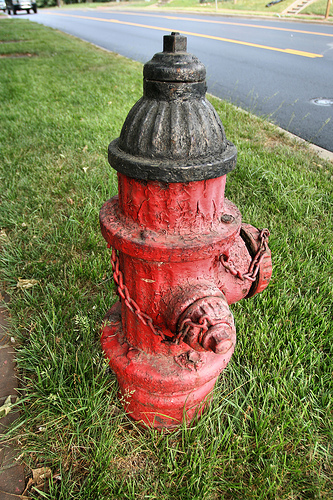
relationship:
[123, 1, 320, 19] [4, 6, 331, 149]
sidewalk runs along road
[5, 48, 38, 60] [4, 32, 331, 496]
hole in grass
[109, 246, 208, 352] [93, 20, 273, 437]
chain on fire hydrant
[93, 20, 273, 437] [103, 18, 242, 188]
fire hydrant has hydrant top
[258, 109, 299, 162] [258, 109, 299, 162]
curb at curb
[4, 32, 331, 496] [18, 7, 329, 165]
grass on either side of street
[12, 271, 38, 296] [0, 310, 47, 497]
leave on cement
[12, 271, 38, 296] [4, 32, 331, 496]
leave on grass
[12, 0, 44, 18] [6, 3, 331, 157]
car drives on street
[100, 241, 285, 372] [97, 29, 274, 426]
chain connecting valves on fire hydrant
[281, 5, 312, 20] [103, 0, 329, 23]
steps lead up a hill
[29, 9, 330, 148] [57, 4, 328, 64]
street divided by lines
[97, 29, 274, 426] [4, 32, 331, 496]
fire hydrant in grass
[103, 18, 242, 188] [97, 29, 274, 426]
hydrant top of fire hydrant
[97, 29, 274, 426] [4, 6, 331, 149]
fire hydrant beside road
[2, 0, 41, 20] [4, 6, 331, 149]
car driving on road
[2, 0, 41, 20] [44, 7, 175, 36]
car on road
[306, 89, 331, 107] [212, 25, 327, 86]
utility access on road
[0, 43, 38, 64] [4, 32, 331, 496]
hole in grass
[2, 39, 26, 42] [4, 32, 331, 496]
hole in grass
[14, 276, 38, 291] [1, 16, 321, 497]
leave are on ground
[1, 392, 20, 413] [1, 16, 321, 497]
leave are on ground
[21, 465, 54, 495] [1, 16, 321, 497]
leave are on ground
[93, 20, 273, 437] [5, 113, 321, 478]
fire hydrant surrounded by grass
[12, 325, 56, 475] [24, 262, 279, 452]
cement by grass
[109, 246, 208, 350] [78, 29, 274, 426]
chain are on hydrant